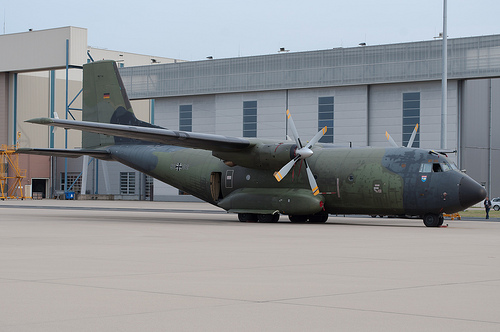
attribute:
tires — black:
[212, 173, 464, 243]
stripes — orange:
[272, 171, 282, 181]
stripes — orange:
[312, 185, 322, 196]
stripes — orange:
[285, 109, 294, 123]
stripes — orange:
[322, 123, 331, 135]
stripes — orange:
[384, 128, 397, 143]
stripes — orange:
[380, 122, 392, 146]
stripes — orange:
[318, 123, 330, 139]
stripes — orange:
[279, 105, 299, 131]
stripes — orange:
[305, 175, 321, 200]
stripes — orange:
[265, 156, 287, 186]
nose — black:
[462, 172, 486, 209]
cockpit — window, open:
[422, 160, 447, 176]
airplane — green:
[17, 60, 487, 227]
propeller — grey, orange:
[263, 99, 340, 225]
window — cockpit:
[420, 161, 454, 172]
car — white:
[486, 192, 498, 204]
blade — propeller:
[302, 156, 319, 196]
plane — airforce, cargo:
[11, 58, 486, 226]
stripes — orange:
[273, 108, 333, 198]